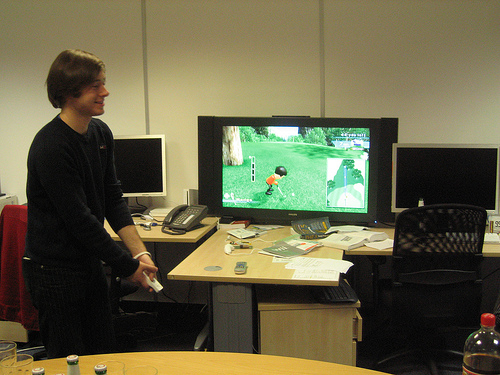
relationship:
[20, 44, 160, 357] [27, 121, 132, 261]
person wearing shirt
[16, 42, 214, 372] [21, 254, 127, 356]
man wearing pants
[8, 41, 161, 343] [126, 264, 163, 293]
man holding controller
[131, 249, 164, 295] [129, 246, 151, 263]
wii remote connected to wrist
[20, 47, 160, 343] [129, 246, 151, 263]
man has wrist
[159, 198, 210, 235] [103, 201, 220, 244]
telephone on table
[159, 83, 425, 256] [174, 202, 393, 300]
tv on table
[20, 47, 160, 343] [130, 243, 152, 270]
man has wrist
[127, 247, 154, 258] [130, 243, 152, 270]
band on wrist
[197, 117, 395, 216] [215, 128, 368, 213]
tv playing game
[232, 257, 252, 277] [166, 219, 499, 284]
cell phone on table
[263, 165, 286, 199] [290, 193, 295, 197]
wii golfer striking ball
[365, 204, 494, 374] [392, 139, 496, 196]
chair facing monitor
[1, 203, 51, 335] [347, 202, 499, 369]
jacket covering chair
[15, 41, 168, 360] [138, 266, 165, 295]
boy holding controller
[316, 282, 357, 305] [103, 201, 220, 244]
keyboard under table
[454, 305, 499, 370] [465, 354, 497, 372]
bottle of soda